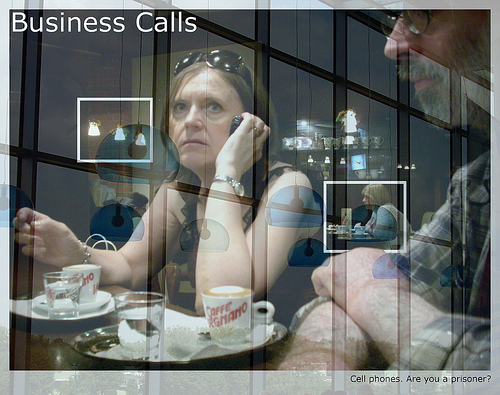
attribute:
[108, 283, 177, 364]
glass — clear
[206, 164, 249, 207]
watch — woman's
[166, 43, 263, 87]
sunglasses — dark, black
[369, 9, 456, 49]
eyeglasses — man's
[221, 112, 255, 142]
cellphone — black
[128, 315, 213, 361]
piece — white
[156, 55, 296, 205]
hair — woman's, brown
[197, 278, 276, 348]
cup — small, tea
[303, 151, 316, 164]
lamp — wall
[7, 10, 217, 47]
calls — business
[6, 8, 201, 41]
calls — business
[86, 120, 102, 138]
light — white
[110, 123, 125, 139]
light — white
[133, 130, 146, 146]
light — white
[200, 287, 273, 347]
cup — white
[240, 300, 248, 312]
letter — red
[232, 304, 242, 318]
letter — red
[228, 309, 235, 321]
letter — red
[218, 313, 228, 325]
letter — red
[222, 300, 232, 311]
letter — red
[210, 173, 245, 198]
watch — silver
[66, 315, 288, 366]
plate — silver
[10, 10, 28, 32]
letter — white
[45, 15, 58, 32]
letter — white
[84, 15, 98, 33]
letter — white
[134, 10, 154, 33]
letter — white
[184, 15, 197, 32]
letter — white